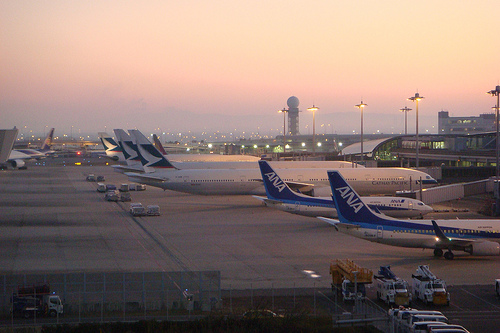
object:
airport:
[19, 93, 486, 324]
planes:
[116, 115, 478, 271]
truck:
[308, 241, 391, 331]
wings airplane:
[431, 215, 474, 265]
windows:
[290, 175, 335, 187]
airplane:
[119, 128, 439, 210]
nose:
[420, 172, 440, 190]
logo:
[365, 177, 414, 195]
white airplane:
[135, 163, 430, 197]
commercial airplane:
[104, 125, 441, 202]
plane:
[242, 160, 436, 216]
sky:
[4, 2, 495, 144]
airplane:
[325, 167, 496, 258]